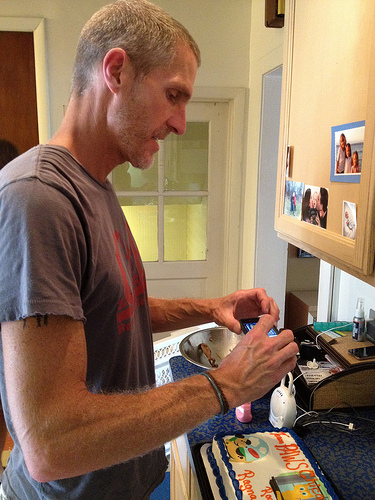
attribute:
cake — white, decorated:
[205, 458, 316, 486]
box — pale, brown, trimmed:
[278, 312, 370, 415]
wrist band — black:
[199, 366, 228, 416]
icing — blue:
[234, 437, 326, 477]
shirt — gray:
[0, 143, 170, 498]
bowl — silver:
[177, 325, 246, 370]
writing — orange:
[273, 438, 305, 472]